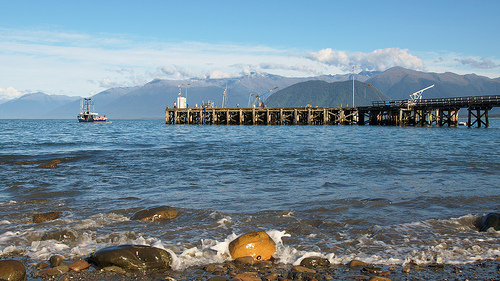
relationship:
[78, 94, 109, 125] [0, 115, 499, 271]
ship in water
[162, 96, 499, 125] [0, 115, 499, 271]
bridge in water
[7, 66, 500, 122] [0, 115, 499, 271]
mountains behind water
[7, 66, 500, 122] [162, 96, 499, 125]
mountains behind bridge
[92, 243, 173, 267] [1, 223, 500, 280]
stone on shore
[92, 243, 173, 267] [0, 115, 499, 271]
stone in water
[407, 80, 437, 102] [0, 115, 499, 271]
crane by water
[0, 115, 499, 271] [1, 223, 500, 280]
water hitting shore